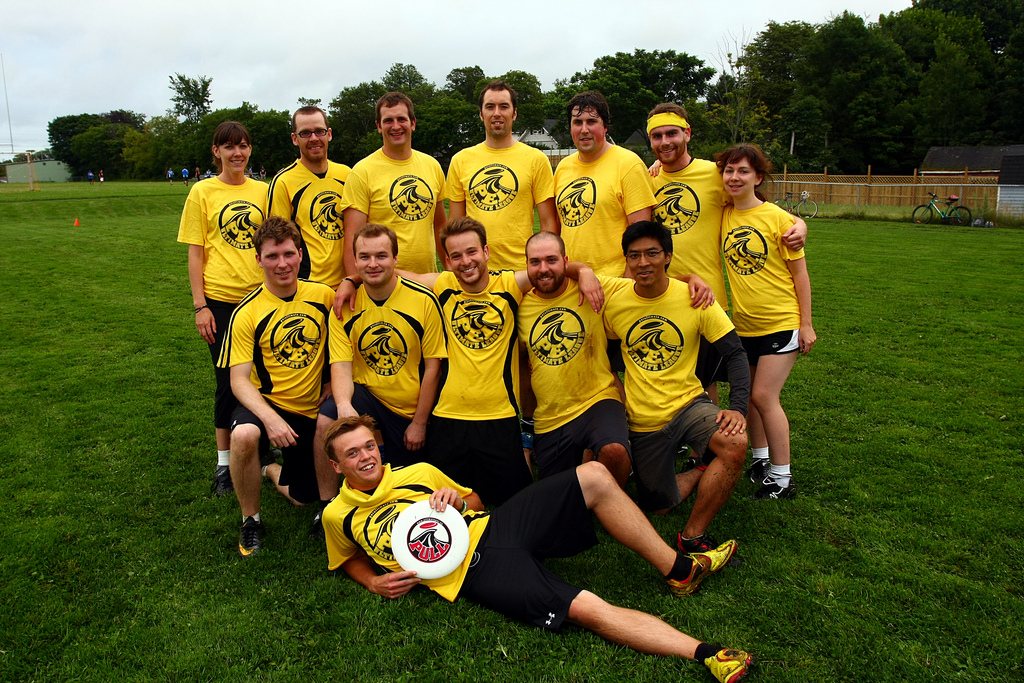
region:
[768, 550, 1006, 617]
the field looks green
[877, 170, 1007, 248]
A bicycle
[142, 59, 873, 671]
Ultimate frisbee team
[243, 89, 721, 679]
Eleven men in yellow shirts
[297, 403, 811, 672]
Man holding a frisbee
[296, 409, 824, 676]
Man in yellow shirt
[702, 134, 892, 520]
Woman in a yellow shirt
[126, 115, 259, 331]
woman in a yellow shirt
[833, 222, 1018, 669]
Green, grassy field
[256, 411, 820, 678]
Man laying on the ground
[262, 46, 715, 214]
Five men standing together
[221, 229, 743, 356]
Five men kneeling together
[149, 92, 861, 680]
a group of young men and women wearing yellow shirts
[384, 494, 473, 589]
a frisbe disc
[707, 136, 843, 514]
a young woman wearing shorts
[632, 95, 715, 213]
a man wearing a yellow sweat band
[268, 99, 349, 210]
a man wearing glasses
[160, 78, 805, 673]
a sports team posing for a photograph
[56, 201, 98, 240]
orange cone on a field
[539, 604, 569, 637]
an Under Armour logo on a pair of shorts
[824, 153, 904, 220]
a wooden fence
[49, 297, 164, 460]
Grass is green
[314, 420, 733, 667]
Boy laying down on grass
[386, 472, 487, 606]
A white frisbee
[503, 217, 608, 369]
Man has beard and mustache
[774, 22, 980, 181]
Trees in the background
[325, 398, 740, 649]
Guy is wearing black shorts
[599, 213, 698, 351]
Guy has black hair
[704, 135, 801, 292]
Young woman has brown hair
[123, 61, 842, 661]
A group posing together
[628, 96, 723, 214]
Guy wearing a yellow headband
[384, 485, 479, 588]
a white frisbee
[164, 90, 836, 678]
an ultimate frisbee team posing for a picture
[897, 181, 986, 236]
a green bike parked by a fence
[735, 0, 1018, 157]
a group of trees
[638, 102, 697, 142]
a yellow headband on the head of one of the players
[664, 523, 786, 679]
yellow tennis shoes on one of the players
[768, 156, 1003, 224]
a wooden privacy fence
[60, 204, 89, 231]
an orange traffic cone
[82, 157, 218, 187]
a group of people playing a game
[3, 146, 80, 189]
a grey building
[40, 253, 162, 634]
Lush, green, manicured grass.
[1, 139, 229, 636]
Uneven playing field,extends far away, reveals cleft.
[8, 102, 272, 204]
People trees and edifice in distance.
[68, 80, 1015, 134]
Row of trees abutting field.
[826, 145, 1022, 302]
Fence, domicile and bike.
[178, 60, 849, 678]
Large grouping, wearing sports-style uniform.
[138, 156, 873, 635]
All in yellow and black.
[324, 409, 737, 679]
Smiling, reclining, redheaded male, grasps Frisbee.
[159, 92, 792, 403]
A predominance of males, includes two females.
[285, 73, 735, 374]
Four bearded individuals, one wearing headband.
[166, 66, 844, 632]
a Frisbee team wearing yellow uniforms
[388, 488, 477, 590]
a white Frisbee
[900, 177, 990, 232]
a bicycle in front of a wooden fence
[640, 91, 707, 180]
a man wearing a yellow headband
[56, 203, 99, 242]
an orange cone on green grass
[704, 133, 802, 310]
a smiling woman in a yellow shirt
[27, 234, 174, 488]
green grass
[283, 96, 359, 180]
a smiling man wearing glasses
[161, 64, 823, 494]
a group picture for a sport's team